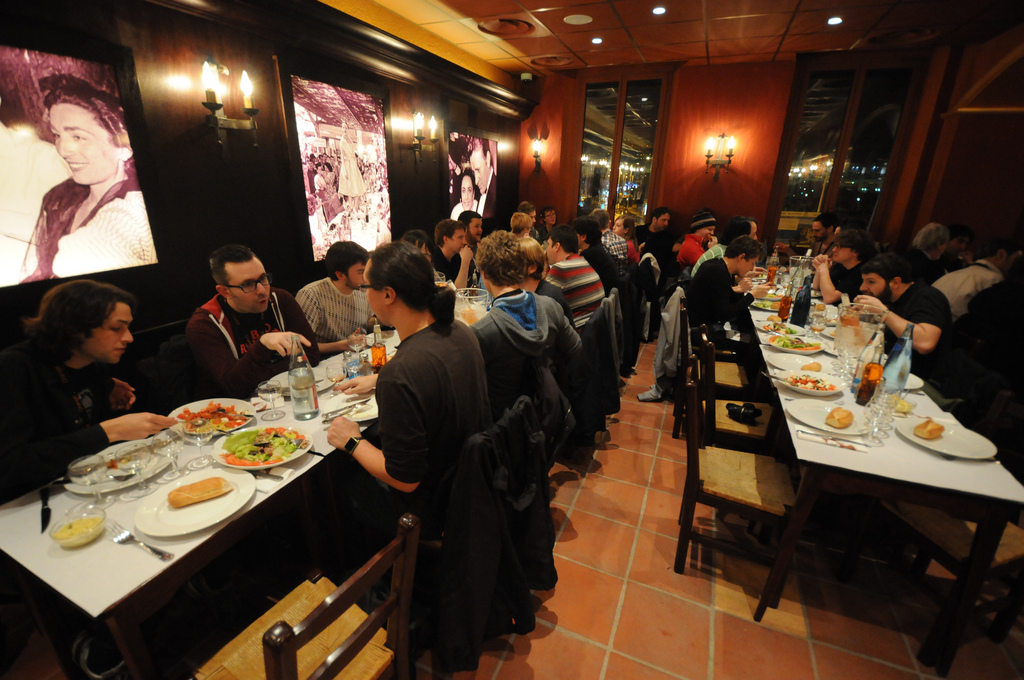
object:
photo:
[0, 45, 162, 288]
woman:
[27, 72, 160, 278]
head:
[209, 245, 272, 313]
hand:
[258, 331, 312, 358]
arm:
[183, 319, 274, 399]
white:
[188, 505, 218, 521]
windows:
[830, 39, 939, 251]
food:
[218, 426, 309, 465]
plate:
[210, 426, 314, 470]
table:
[0, 171, 610, 674]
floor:
[614, 461, 688, 675]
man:
[183, 243, 320, 405]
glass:
[290, 348, 312, 420]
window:
[613, 78, 662, 230]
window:
[577, 80, 616, 238]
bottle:
[283, 337, 320, 422]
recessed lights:
[639, 5, 679, 20]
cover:
[795, 425, 870, 453]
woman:
[5, 290, 178, 482]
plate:
[61, 439, 176, 494]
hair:
[208, 245, 257, 286]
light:
[202, 62, 229, 118]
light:
[233, 65, 265, 115]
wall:
[2, 6, 530, 406]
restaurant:
[2, 4, 1024, 676]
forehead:
[228, 262, 263, 280]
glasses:
[219, 272, 274, 294]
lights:
[702, 135, 718, 175]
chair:
[186, 506, 424, 678]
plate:
[131, 463, 257, 540]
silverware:
[102, 521, 174, 562]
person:
[2, 275, 188, 489]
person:
[288, 240, 379, 357]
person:
[325, 243, 496, 543]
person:
[466, 225, 587, 401]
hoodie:
[469, 290, 586, 433]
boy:
[463, 228, 582, 432]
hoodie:
[183, 282, 320, 400]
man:
[849, 260, 955, 386]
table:
[733, 258, 1024, 678]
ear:
[214, 284, 230, 300]